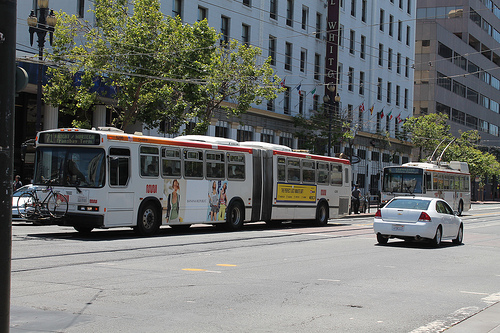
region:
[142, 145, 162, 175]
a window on a bus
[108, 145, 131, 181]
a window on a bus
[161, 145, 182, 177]
a window on a bus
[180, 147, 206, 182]
a window on a bus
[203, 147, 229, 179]
a window on a bus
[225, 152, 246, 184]
a window on a bus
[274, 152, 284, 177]
a window on a bus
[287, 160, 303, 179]
a window on a bus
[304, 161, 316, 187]
a window on a bus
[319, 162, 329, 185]
a window on a bus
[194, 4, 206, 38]
a window on a house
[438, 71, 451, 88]
a window on a house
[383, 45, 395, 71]
a window on a house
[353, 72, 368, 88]
a window on a house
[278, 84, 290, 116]
a window on a house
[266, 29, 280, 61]
a window on a house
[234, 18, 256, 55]
a window on a house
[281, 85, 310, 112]
a window on a house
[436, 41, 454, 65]
a window on a house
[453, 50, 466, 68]
a window on a house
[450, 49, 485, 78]
part of some wires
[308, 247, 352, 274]
part of a road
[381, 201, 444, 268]
back of a car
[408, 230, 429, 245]
part of an exhaust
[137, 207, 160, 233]
part of a rim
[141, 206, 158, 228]
part of a wheel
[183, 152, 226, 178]
part of a window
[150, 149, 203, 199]
side of a bus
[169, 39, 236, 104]
part of a tree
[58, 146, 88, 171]
part of a window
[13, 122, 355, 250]
An extra long bus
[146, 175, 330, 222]
Advertising on the side of a bus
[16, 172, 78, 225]
A bike riding the bus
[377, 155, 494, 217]
A normal size bus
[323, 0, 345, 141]
A business sign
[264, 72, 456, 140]
A row of various flags on the side of a building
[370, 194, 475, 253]
A white car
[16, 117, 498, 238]
Two buses going in the same direction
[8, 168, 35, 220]
A pedestrian by a parked car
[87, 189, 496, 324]
Hardly any traffic going this direction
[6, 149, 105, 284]
Bike on front of bus.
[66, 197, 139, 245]
Lights on front of bus.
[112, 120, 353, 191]
Red stripe around top of bus.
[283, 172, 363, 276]
Yellow and blue sign on bus.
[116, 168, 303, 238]
Bus is mostly white in color.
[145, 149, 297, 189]
Windows line side of bus.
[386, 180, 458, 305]
White car on opposite side of the street from bus.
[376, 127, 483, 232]
Bus behind the long bus.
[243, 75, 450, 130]
Flags on the side of the building.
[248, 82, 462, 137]
Large buildings line the street.